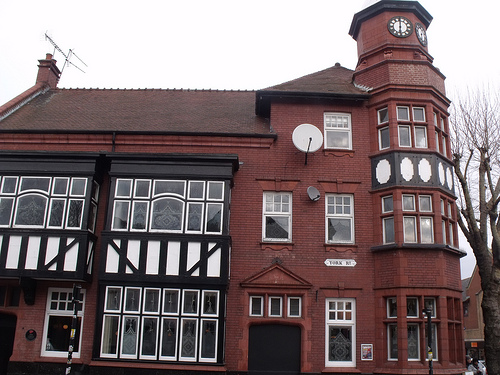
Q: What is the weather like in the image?
A: It is cloudy.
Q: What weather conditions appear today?
A: It is cloudy.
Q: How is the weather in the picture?
A: It is cloudy.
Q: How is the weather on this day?
A: It is cloudy.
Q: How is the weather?
A: It is cloudy.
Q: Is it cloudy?
A: Yes, it is cloudy.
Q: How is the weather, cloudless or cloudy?
A: It is cloudy.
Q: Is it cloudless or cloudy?
A: It is cloudy.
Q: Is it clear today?
A: No, it is cloudy.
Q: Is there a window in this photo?
A: Yes, there are windows.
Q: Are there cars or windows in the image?
A: Yes, there are windows.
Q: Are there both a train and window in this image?
A: No, there are windows but no trains.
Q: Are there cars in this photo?
A: No, there are no cars.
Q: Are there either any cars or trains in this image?
A: No, there are no cars or trains.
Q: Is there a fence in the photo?
A: No, there are no fences.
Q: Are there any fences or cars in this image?
A: No, there are no fences or cars.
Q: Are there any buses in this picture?
A: No, there are no buses.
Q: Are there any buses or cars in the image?
A: No, there are no buses or cars.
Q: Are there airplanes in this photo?
A: No, there are no airplanes.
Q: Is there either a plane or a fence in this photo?
A: No, there are no airplanes or fences.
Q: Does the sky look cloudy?
A: Yes, the sky is cloudy.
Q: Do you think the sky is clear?
A: No, the sky is cloudy.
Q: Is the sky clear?
A: No, the sky is cloudy.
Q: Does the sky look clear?
A: No, the sky is cloudy.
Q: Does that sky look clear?
A: No, the sky is cloudy.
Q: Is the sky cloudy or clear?
A: The sky is cloudy.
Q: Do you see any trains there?
A: No, there are no trains.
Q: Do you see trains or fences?
A: No, there are no trains or fences.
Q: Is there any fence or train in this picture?
A: No, there are no trains or fences.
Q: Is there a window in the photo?
A: Yes, there are windows.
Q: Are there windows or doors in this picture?
A: Yes, there are windows.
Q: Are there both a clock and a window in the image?
A: Yes, there are both a window and a clock.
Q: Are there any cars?
A: No, there are no cars.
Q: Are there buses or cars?
A: No, there are no cars or buses.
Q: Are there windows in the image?
A: Yes, there are windows.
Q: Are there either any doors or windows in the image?
A: Yes, there are windows.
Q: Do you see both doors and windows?
A: Yes, there are both windows and a door.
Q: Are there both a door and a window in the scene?
A: Yes, there are both a window and a door.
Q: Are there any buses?
A: No, there are no buses.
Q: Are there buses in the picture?
A: No, there are no buses.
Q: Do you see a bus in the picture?
A: No, there are no buses.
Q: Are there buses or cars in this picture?
A: No, there are no buses or cars.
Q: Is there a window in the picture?
A: Yes, there is a window.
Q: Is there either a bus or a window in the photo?
A: Yes, there is a window.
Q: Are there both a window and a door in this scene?
A: Yes, there are both a window and a door.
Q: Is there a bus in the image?
A: No, there are no buses.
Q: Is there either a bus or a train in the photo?
A: No, there are no buses or trains.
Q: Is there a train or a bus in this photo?
A: No, there are no buses or trains.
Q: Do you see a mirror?
A: No, there are no mirrors.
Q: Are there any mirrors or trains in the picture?
A: No, there are no mirrors or trains.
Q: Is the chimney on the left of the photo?
A: Yes, the chimney is on the left of the image.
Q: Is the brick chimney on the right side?
A: No, the chimney is on the left of the image.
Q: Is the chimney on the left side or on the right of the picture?
A: The chimney is on the left of the image.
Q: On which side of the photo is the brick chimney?
A: The chimney is on the left of the image.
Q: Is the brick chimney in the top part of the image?
A: Yes, the chimney is in the top of the image.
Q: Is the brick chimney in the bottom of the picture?
A: No, the chimney is in the top of the image.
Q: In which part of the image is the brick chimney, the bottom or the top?
A: The chimney is in the top of the image.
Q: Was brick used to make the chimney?
A: Yes, the chimney is made of brick.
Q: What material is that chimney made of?
A: The chimney is made of brick.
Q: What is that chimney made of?
A: The chimney is made of brick.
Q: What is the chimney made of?
A: The chimney is made of brick.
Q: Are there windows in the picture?
A: Yes, there are windows.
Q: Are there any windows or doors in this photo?
A: Yes, there are windows.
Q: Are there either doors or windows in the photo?
A: Yes, there are windows.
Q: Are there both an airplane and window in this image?
A: No, there are windows but no airplanes.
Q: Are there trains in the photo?
A: No, there are no trains.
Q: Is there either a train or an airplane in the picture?
A: No, there are no trains or airplanes.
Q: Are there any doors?
A: Yes, there is a door.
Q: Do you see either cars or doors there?
A: Yes, there is a door.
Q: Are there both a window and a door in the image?
A: Yes, there are both a door and a window.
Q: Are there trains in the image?
A: No, there are no trains.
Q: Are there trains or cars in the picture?
A: No, there are no trains or cars.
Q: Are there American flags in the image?
A: No, there are no American flags.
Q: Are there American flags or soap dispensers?
A: No, there are no American flags or soap dispensers.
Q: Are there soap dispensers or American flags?
A: No, there are no American flags or soap dispensers.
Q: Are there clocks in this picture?
A: Yes, there is a clock.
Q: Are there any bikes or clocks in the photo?
A: Yes, there is a clock.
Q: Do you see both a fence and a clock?
A: No, there is a clock but no fences.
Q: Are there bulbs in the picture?
A: No, there are no bulbs.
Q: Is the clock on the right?
A: Yes, the clock is on the right of the image.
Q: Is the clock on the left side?
A: No, the clock is on the right of the image.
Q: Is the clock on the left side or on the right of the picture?
A: The clock is on the right of the image.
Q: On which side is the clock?
A: The clock is on the right of the image.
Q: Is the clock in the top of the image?
A: Yes, the clock is in the top of the image.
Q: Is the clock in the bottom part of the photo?
A: No, the clock is in the top of the image.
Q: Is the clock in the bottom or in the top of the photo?
A: The clock is in the top of the image.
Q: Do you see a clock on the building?
A: Yes, there is a clock on the building.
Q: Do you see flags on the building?
A: No, there is a clock on the building.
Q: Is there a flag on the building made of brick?
A: No, there is a clock on the building.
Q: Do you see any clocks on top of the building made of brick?
A: Yes, there is a clock on top of the building.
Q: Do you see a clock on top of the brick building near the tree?
A: Yes, there is a clock on top of the building.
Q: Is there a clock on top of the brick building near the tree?
A: Yes, there is a clock on top of the building.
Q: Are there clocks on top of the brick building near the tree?
A: Yes, there is a clock on top of the building.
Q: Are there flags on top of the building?
A: No, there is a clock on top of the building.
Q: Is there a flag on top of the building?
A: No, there is a clock on top of the building.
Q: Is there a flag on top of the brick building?
A: No, there is a clock on top of the building.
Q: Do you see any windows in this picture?
A: Yes, there are windows.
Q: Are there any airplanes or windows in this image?
A: Yes, there are windows.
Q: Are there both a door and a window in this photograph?
A: Yes, there are both a window and a door.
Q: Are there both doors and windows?
A: Yes, there are both windows and a door.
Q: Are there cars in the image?
A: No, there are no cars.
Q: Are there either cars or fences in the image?
A: No, there are no cars or fences.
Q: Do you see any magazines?
A: No, there are no magazines.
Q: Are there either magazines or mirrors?
A: No, there are no magazines or mirrors.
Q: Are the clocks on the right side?
A: Yes, the clocks are on the right of the image.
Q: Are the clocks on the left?
A: No, the clocks are on the right of the image.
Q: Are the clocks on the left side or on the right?
A: The clocks are on the right of the image.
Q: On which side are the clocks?
A: The clocks are on the right of the image.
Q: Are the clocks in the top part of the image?
A: Yes, the clocks are in the top of the image.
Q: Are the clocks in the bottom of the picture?
A: No, the clocks are in the top of the image.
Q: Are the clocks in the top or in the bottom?
A: The clocks are in the top of the image.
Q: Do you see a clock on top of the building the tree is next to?
A: Yes, there are clocks on top of the building.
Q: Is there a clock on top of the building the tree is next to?
A: Yes, there are clocks on top of the building.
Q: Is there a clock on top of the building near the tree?
A: Yes, there are clocks on top of the building.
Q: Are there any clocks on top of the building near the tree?
A: Yes, there are clocks on top of the building.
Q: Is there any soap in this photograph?
A: No, there are no soaps.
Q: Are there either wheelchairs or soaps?
A: No, there are no soaps or wheelchairs.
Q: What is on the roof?
A: The antennas are on the roof.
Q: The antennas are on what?
A: The antennas are on the roof.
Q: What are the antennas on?
A: The antennas are on the roof.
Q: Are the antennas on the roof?
A: Yes, the antennas are on the roof.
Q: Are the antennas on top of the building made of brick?
A: Yes, the antennas are on top of the building.